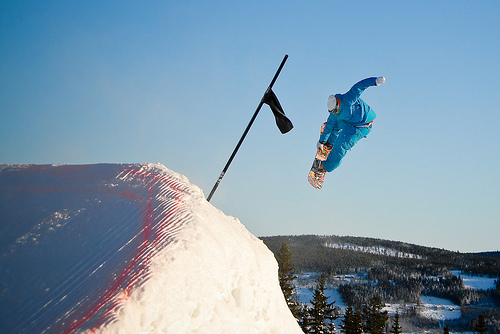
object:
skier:
[305, 75, 389, 193]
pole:
[203, 45, 303, 222]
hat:
[325, 91, 339, 113]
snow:
[197, 226, 223, 253]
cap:
[30, 160, 282, 310]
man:
[303, 70, 385, 189]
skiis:
[192, 55, 300, 200]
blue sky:
[3, 0, 498, 254]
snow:
[1, 162, 305, 332]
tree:
[267, 237, 302, 322]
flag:
[201, 52, 296, 203]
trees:
[381, 303, 406, 331]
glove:
[369, 76, 394, 93]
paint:
[16, 167, 181, 332]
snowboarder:
[307, 73, 385, 189]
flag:
[262, 87, 298, 137]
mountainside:
[267, 227, 496, 334]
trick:
[293, 71, 388, 194]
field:
[4, 154, 323, 332]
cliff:
[194, 180, 364, 330]